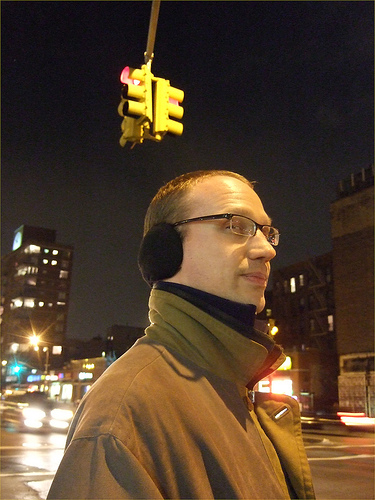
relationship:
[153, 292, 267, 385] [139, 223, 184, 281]
collar below muff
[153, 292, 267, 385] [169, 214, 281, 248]
collar below glasses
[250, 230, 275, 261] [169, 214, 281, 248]
nose below glasses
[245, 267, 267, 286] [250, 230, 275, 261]
lips are below nose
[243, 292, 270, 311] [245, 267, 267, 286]
chin below lips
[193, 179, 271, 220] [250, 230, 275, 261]
forehead above nose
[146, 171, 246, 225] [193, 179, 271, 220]
hair above forehead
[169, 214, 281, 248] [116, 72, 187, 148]
glasses are below stoplight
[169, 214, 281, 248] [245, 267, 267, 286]
glasses are above lips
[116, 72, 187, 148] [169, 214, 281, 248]
stoplight above glasses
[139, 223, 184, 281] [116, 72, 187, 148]
muff below stoplight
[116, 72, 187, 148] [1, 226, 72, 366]
stoplight far from building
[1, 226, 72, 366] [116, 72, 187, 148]
building left of stoplight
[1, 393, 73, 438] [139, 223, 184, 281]
car left of muff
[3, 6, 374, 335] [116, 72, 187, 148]
sky above stoplight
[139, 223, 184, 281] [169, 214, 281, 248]
muff are level with glasses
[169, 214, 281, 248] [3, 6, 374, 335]
glasses are beneath sky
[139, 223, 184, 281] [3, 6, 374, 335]
muff beneath sky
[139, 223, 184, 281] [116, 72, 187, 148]
muff beneath stoplight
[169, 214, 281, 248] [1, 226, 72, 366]
glasses are to right of building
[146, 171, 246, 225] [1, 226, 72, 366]
hair right of building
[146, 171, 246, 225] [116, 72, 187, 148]
hair beneath stoplight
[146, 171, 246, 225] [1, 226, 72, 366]
hair beneath building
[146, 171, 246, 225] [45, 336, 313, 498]
hair above jacket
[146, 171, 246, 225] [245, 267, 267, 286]
hair above lips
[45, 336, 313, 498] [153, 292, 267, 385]
jacket beneath collar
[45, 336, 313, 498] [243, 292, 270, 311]
jacket beneath chin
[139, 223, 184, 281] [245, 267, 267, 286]
muff left of lips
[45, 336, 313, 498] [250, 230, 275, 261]
jacket beneath nose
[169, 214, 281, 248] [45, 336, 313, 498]
glasses are above jacket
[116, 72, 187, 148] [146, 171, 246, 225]
stoplight above hair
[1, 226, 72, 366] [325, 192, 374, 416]
building across from other building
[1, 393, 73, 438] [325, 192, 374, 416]
car across from other building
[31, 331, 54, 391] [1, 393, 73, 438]
street lamp above car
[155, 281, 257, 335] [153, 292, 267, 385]
turtleneck above collar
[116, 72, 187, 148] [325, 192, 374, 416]
stoplight left of other building